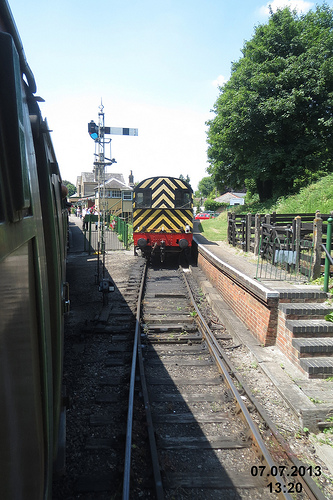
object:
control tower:
[82, 99, 140, 307]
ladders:
[272, 287, 332, 381]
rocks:
[104, 250, 130, 309]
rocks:
[230, 324, 254, 355]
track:
[120, 257, 299, 499]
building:
[94, 176, 134, 223]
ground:
[216, 239, 229, 262]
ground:
[101, 262, 131, 308]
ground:
[69, 376, 116, 497]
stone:
[239, 394, 248, 402]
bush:
[176, 0, 332, 198]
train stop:
[0, 0, 333, 500]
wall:
[12, 225, 61, 294]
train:
[131, 175, 195, 262]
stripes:
[146, 209, 187, 224]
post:
[323, 218, 331, 293]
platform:
[199, 234, 320, 302]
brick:
[245, 309, 257, 333]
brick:
[266, 318, 278, 338]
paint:
[33, 245, 45, 289]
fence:
[224, 209, 322, 279]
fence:
[81, 213, 126, 252]